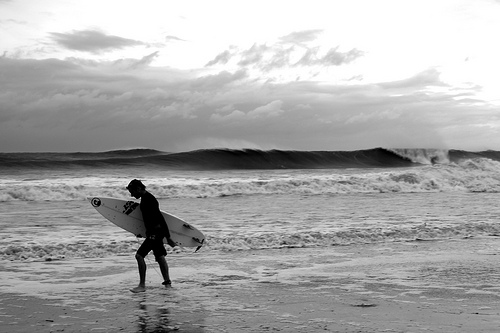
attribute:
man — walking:
[126, 177, 181, 295]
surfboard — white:
[90, 195, 210, 254]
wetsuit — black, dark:
[133, 198, 171, 259]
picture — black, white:
[2, 5, 495, 332]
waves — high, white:
[217, 153, 490, 239]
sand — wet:
[266, 292, 302, 326]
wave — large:
[343, 148, 495, 176]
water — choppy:
[243, 148, 466, 189]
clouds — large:
[46, 26, 378, 140]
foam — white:
[349, 172, 494, 197]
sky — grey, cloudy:
[216, 8, 472, 131]